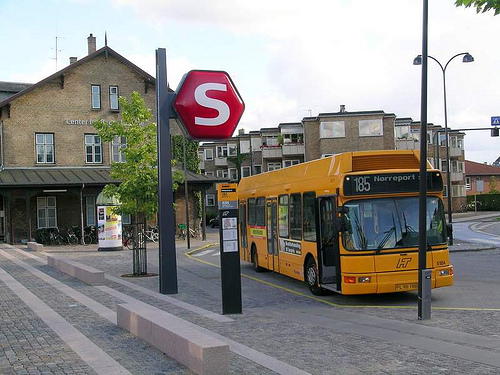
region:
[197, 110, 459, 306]
The bus is at the terminal.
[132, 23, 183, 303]
The pole is black.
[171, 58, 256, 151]
A red and white sign is attached to the pole.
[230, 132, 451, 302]
The bus is yellow.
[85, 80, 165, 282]
A little green tree.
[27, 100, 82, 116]
The building is made out of bricks.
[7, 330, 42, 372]
Cobblestones on the ground.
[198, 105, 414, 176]
Some buildings in the distance.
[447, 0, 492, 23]
The leaves are green.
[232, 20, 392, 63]
The sky is overcast.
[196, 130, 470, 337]
a yellow bus parked next to the curb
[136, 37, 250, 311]
a red sign with the letter S on it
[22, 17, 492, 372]
a scene of downtown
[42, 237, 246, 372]
a couple stone slabs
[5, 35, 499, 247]
a couple of buildings in the background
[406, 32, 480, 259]
a lamppost that is gray and in the distance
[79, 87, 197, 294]
a green tree in front of the building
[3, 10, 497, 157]
a sky that has clouds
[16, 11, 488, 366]
a scene happening during the day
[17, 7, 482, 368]
a scene outside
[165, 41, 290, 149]
red and white sign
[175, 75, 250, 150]
the letter s on a sign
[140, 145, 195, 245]
pole holding a sign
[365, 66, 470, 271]
pole on the ground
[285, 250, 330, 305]
front tire of bus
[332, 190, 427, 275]
front window of bus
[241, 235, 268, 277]
back tire of bus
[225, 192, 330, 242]
side windows on the bus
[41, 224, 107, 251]
bikes in the background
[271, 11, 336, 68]
sky above the building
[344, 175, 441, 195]
The marquee display on the front of the bus.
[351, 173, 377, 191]
The numbers on the marquee display of the bus.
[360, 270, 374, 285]
The left white headlight of the bus.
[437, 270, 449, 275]
The right white headlight of the bus.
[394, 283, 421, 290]
The yellow license plate on the front of the bus.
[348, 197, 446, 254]
The front window of the bus.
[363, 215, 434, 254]
The windshield wipers on the front window.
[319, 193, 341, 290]
The open door of the bus.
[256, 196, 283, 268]
The double doors in the middle of the bus.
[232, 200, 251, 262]
The double doors in the back of the bus.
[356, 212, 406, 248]
part of a window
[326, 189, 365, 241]
part of a window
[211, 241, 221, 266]
edge of a post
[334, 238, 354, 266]
edge of a bus